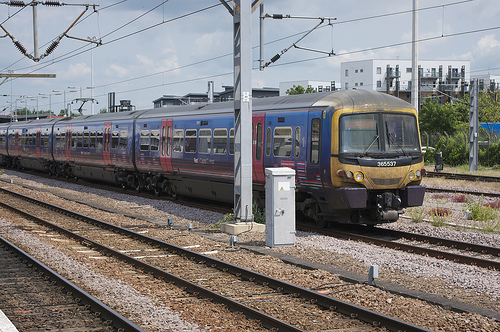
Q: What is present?
A: A train.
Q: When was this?
A: Daytime.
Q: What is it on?
A: Rail tracks.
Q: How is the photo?
A: Clear.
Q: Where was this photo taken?
A: Train yard.